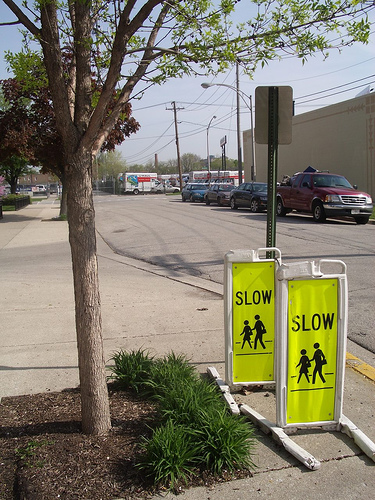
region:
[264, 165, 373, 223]
red truck parked along street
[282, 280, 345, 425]
yellow and black slow crossing sign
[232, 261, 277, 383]
yellow and black slow crossing sign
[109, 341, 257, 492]
green plants growing under tree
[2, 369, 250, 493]
square patch of mulch under tree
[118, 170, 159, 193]
orange and white Uhaul van parked in lot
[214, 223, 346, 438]
two yellow and white signs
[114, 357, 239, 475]
green planted grass by tree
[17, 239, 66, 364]
grey concrete sidewalk by road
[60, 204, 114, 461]
trunk of small tree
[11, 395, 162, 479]
mulched area around tree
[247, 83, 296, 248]
back of white sign on green post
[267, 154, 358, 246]
red truck across street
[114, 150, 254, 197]
lot of uhaul trucks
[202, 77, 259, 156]
grey street light post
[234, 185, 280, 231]
dark colored car behind truck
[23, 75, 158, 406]
the tree is tall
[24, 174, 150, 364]
the tree is thin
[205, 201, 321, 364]
the signs are neon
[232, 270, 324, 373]
the signs are green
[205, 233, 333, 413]
the signs are yellow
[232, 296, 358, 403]
the text is black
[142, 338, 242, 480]
the bushes are small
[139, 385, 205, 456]
the small bushes are green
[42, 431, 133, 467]
this is bark dust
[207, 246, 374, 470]
two yellow pedestrian crossing signs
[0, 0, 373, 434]
a row of trees on the street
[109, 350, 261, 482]
tufts of grass next to the tree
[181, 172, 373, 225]
cars parked on the street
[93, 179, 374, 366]
a quiet city street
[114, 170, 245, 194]
parking lot full of moving trucks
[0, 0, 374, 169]
blue sky above the scene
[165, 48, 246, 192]
two wooden telephone poles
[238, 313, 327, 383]
pictures on the crossing signs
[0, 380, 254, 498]
bark dust under the tree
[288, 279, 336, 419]
a yellow street sign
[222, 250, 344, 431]
two street signs next to each other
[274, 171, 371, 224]
a red pick up truck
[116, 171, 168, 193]
white uhaul truck behind a fence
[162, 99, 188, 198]
a long leaning phone pole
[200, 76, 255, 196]
a tall street light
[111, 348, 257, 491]
a small cluster of green plants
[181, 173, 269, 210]
a row of small sudans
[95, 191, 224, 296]
an empty city street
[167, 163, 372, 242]
the cars are parked